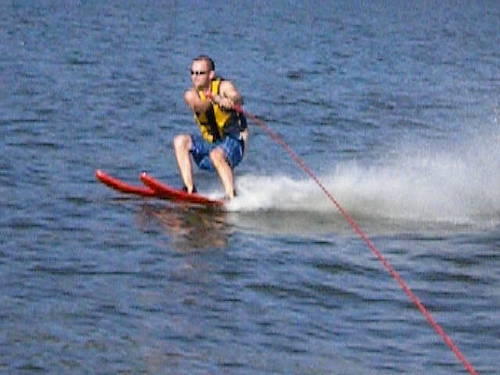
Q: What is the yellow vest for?
A: Flotation.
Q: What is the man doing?
A: Waterskiing.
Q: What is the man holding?
A: Rope to boat.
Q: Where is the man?
A: Lake.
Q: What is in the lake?
A: Water.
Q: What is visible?
A: A surf board.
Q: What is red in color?
A: Surf board.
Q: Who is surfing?
A: A man.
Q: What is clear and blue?
A: Water.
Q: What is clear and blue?
A: Water.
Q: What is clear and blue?
A: Water.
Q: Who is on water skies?
A: A man.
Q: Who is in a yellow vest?
A: A man.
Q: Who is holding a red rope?
A: A man.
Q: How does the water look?
A: Calm.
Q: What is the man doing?
A: Water skiing.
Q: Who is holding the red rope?
A: The skier.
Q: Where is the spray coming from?
A: The skis.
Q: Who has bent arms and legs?
A: The man.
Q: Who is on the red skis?
A: The man.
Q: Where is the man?
A: In the water.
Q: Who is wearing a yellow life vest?
A: The skier.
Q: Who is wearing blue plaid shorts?
A: The skier.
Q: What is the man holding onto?
A: A rope.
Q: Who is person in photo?
A: Man.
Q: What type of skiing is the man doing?
A: Water skiing.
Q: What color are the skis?
A: Orange.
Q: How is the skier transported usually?
A: By boat.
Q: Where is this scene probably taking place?
A: Lake.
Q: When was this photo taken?
A: Daytime.